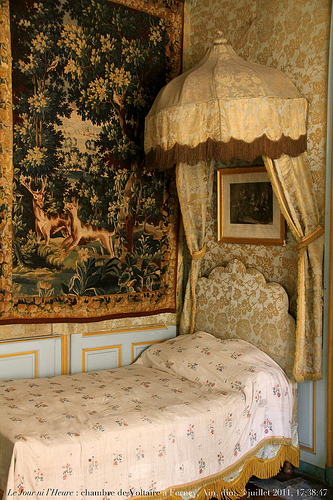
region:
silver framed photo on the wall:
[215, 165, 286, 245]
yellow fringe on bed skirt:
[180, 443, 301, 498]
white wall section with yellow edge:
[1, 332, 69, 386]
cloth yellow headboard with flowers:
[194, 258, 298, 421]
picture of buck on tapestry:
[20, 173, 78, 248]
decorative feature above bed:
[143, 29, 309, 163]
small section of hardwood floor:
[215, 470, 329, 498]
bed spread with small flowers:
[1, 331, 292, 497]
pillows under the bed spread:
[141, 329, 288, 397]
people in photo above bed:
[235, 183, 269, 221]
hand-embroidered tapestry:
[1, 0, 186, 331]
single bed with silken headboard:
[2, 259, 300, 494]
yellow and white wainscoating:
[0, 330, 186, 375]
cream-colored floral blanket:
[2, 331, 298, 487]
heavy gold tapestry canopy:
[143, 28, 325, 384]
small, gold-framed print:
[212, 164, 290, 247]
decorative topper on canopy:
[211, 28, 226, 47]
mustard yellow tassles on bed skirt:
[118, 429, 308, 499]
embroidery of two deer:
[18, 171, 127, 259]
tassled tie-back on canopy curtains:
[291, 223, 328, 248]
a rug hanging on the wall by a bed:
[0, 1, 188, 340]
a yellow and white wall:
[0, 315, 180, 385]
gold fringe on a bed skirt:
[135, 442, 305, 499]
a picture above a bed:
[210, 164, 295, 250]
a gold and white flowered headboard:
[186, 257, 313, 373]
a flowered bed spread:
[3, 330, 302, 498]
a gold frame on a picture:
[210, 166, 290, 252]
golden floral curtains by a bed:
[262, 154, 325, 381]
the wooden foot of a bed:
[280, 459, 296, 478]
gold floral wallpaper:
[183, 0, 327, 319]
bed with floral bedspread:
[0, 341, 294, 498]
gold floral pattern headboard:
[184, 258, 300, 386]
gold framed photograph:
[216, 168, 284, 243]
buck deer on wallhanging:
[17, 173, 62, 244]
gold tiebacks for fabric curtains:
[290, 221, 327, 250]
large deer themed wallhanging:
[4, 0, 184, 323]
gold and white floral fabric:
[189, 0, 332, 30]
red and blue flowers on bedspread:
[201, 345, 210, 358]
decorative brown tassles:
[247, 136, 306, 157]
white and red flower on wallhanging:
[77, 248, 90, 262]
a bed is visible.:
[169, 387, 213, 442]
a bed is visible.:
[133, 429, 165, 466]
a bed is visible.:
[75, 328, 243, 436]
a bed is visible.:
[69, 363, 206, 486]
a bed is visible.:
[88, 337, 277, 488]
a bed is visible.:
[119, 396, 293, 497]